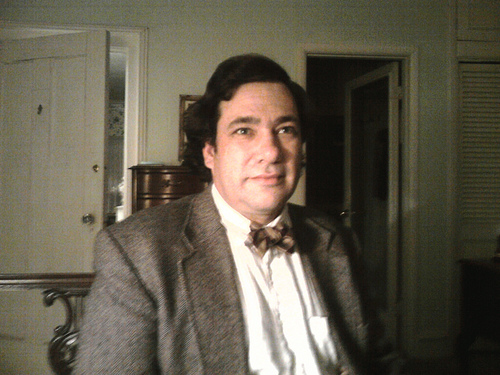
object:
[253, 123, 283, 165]
nose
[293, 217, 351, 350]
lapel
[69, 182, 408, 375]
jacket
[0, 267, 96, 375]
chair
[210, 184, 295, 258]
collar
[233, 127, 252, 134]
eye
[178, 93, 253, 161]
picture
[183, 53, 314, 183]
hair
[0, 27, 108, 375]
white door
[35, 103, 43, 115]
peep hole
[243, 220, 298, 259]
bow tie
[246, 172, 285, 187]
mouth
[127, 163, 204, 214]
amoire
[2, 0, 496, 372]
room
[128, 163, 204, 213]
drawers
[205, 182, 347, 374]
man's shirt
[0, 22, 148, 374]
door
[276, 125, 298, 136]
eye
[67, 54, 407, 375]
man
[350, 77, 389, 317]
glass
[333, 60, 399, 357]
door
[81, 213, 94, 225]
knob